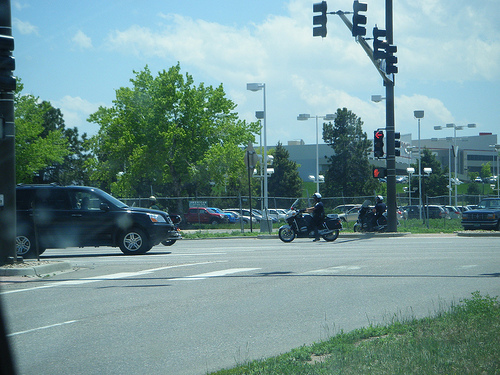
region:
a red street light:
[375, 122, 395, 167]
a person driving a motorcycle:
[263, 192, 353, 244]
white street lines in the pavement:
[110, 261, 318, 304]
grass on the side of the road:
[362, 315, 461, 372]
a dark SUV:
[38, 174, 169, 269]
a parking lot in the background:
[191, 195, 279, 235]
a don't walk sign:
[370, 161, 390, 190]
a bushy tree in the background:
[103, 89, 229, 184]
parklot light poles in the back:
[238, 89, 275, 189]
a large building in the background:
[287, 127, 492, 172]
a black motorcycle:
[273, 199, 345, 241]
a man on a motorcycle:
[281, 189, 343, 243]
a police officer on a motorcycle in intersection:
[279, 189, 346, 246]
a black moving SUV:
[16, 176, 180, 258]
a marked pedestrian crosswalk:
[61, 259, 492, 283]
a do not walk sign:
[369, 166, 386, 180]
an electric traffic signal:
[370, 125, 385, 159]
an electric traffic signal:
[390, 131, 403, 159]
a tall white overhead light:
[291, 110, 338, 203]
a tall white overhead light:
[434, 116, 478, 191]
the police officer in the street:
[261, 184, 348, 249]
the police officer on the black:
[354, 185, 395, 238]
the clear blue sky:
[44, 9, 121, 28]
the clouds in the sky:
[233, 33, 363, 99]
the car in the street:
[9, 172, 182, 257]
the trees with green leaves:
[99, 80, 206, 178]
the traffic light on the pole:
[358, 127, 393, 158]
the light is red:
[360, 122, 390, 165]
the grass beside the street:
[413, 300, 493, 365]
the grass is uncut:
[411, 287, 496, 348]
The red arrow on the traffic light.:
[371, 125, 383, 140]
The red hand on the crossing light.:
[369, 166, 380, 178]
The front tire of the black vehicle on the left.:
[116, 230, 147, 255]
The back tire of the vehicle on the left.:
[7, 227, 33, 254]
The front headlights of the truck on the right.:
[455, 212, 497, 222]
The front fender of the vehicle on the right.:
[461, 220, 499, 235]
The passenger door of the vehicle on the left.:
[67, 183, 112, 233]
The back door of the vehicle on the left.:
[16, 193, 81, 232]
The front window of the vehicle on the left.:
[98, 185, 135, 210]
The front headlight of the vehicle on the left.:
[147, 206, 168, 223]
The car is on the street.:
[0, 157, 213, 272]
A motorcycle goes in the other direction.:
[266, 185, 356, 247]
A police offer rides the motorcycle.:
[293, 180, 344, 246]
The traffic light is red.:
[362, 123, 397, 162]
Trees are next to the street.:
[15, 56, 257, 213]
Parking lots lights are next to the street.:
[239, 68, 451, 234]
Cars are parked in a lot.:
[160, 188, 490, 226]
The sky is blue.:
[10, 1, 256, 99]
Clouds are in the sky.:
[164, 0, 497, 90]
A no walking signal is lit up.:
[360, 160, 399, 187]